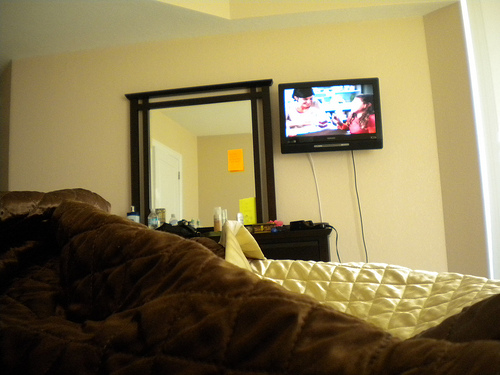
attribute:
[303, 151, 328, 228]
cord — white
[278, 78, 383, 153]
television — on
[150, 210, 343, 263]
dresser — black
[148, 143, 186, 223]
door — white, reflected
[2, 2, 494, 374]
room — messy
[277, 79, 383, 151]
tv — black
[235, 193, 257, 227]
stick note — green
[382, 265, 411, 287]
square — white 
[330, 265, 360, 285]
square — white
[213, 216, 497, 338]
blanket — white, square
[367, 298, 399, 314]
square — white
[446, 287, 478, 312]
square — white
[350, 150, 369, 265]
chord — black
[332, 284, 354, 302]
square — white 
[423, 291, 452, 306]
square — white